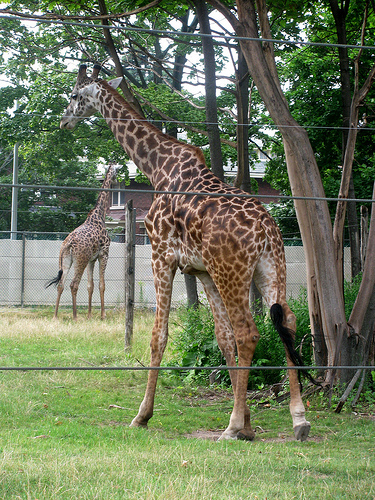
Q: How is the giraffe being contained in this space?
A: With a fence.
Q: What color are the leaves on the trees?
A: Green.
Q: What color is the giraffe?
A: Brown and yellow.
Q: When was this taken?
A: During the day.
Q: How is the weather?
A: It is cloudy.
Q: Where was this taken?
A: At a zoo.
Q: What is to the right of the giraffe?
A: A tree.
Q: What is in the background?
A: Another giraffe.